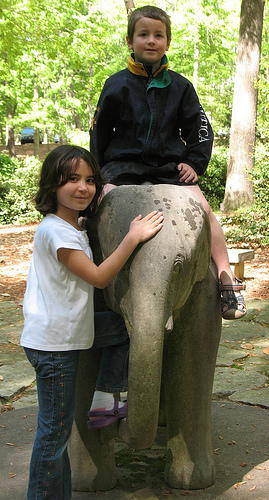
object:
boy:
[89, 6, 247, 321]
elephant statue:
[69, 184, 223, 491]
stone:
[221, 391, 268, 417]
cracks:
[214, 385, 268, 410]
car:
[20, 127, 39, 145]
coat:
[88, 54, 215, 184]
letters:
[199, 105, 209, 145]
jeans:
[22, 345, 82, 499]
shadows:
[1, 297, 268, 499]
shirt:
[21, 213, 97, 353]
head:
[126, 4, 173, 62]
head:
[33, 146, 102, 219]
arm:
[90, 72, 122, 158]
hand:
[178, 161, 198, 186]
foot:
[219, 284, 248, 318]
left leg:
[179, 185, 235, 287]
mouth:
[143, 48, 159, 54]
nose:
[148, 37, 157, 46]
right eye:
[136, 33, 149, 39]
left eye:
[154, 33, 165, 39]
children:
[21, 143, 163, 498]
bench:
[227, 247, 258, 279]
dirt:
[181, 190, 199, 238]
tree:
[220, 0, 265, 209]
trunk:
[120, 249, 168, 452]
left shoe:
[219, 284, 248, 318]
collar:
[127, 54, 172, 83]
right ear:
[124, 35, 132, 48]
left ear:
[166, 37, 172, 49]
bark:
[242, 1, 265, 28]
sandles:
[88, 395, 128, 428]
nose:
[78, 181, 89, 196]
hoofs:
[68, 455, 99, 491]